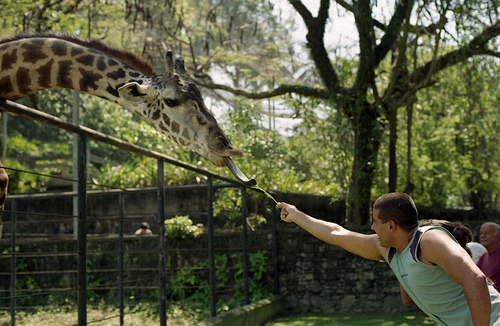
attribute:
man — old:
[470, 214, 495, 308]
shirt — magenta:
[477, 250, 498, 282]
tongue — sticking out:
[212, 151, 324, 195]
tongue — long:
[223, 154, 256, 184]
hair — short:
[373, 192, 417, 232]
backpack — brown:
[421, 205, 469, 231]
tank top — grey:
[381, 224, 498, 322]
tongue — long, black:
[224, 160, 259, 187]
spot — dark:
[54, 58, 73, 88]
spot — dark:
[106, 67, 129, 79]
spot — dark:
[13, 65, 30, 92]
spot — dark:
[50, 38, 70, 57]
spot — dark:
[20, 37, 45, 65]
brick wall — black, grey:
[299, 264, 379, 310]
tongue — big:
[219, 155, 256, 185]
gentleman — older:
[473, 213, 499, 270]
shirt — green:
[379, 221, 498, 318]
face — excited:
[363, 212, 393, 248]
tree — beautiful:
[302, 14, 457, 229]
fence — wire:
[2, 96, 284, 324]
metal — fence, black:
[75, 195, 206, 293]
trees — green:
[253, 16, 487, 186]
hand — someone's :
[273, 194, 298, 227]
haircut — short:
[376, 195, 415, 224]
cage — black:
[30, 101, 280, 314]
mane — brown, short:
[121, 45, 132, 72]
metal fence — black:
[1, 97, 278, 324]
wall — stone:
[246, 180, 356, 314]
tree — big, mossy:
[176, 0, 498, 226]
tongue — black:
[221, 155, 258, 187]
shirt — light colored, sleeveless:
[356, 175, 439, 293]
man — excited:
[270, 188, 495, 322]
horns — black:
[159, 44, 189, 74]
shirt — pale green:
[372, 224, 492, 322]